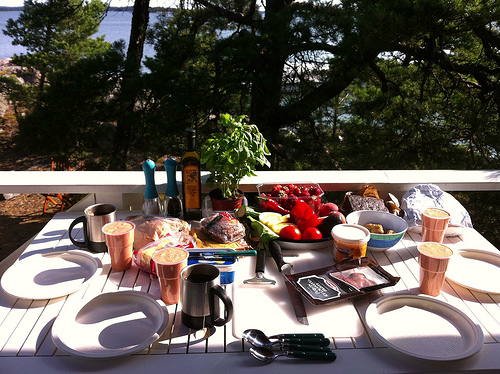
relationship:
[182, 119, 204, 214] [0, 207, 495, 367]
bottle on table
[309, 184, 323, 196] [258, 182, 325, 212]
berry in bowl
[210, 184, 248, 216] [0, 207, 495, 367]
vase on table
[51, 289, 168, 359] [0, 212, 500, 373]
plate on top of picnic table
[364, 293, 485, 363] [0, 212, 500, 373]
bowl on top of picnic table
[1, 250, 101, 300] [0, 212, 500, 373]
plate on top of picnic table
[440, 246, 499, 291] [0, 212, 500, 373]
plate on top of picnic table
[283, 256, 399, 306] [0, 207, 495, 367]
menu on table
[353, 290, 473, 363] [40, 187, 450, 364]
bowl on table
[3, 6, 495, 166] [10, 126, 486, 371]
trees behind porch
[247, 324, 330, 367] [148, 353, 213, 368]
spoons on a table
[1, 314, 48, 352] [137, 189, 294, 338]
boards on picnic table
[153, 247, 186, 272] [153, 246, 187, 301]
drink in a cup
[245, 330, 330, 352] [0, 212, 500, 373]
spoon on picnic table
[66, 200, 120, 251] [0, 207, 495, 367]
mug on table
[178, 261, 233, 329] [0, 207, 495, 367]
mug on table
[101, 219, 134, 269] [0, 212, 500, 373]
cup on picnic table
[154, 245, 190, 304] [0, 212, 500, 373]
cup on picnic table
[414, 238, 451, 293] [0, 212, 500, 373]
cup on picnic table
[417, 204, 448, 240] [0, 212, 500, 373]
cup on picnic table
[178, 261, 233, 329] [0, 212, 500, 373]
mug on picnic table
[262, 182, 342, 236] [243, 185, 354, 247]
vegetables in bowl